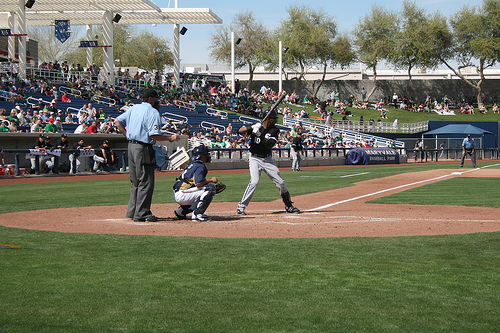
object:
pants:
[123, 142, 162, 223]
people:
[1, 59, 498, 166]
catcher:
[171, 145, 224, 223]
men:
[112, 83, 305, 226]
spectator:
[227, 122, 232, 132]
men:
[1, 53, 378, 153]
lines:
[284, 170, 483, 223]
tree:
[210, 9, 275, 88]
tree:
[254, 5, 356, 97]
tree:
[346, 5, 408, 80]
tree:
[385, 0, 498, 107]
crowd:
[5, 61, 498, 143]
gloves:
[250, 119, 264, 133]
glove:
[249, 120, 264, 130]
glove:
[253, 126, 263, 136]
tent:
[417, 120, 487, 162]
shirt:
[112, 104, 167, 137]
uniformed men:
[170, 145, 225, 221]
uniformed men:
[290, 131, 303, 169]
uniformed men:
[30, 135, 45, 173]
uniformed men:
[93, 137, 114, 173]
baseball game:
[2, 75, 495, 331]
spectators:
[1, 50, 495, 141]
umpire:
[111, 86, 182, 223]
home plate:
[273, 203, 325, 216]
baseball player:
[236, 108, 301, 215]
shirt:
[245, 122, 278, 158]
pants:
[237, 152, 292, 214]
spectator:
[77, 105, 89, 119]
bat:
[252, 87, 288, 135]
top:
[179, 159, 207, 183]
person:
[113, 85, 182, 224]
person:
[234, 113, 299, 220]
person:
[459, 132, 479, 165]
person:
[288, 133, 303, 169]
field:
[6, 159, 482, 331]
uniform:
[106, 103, 168, 220]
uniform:
[233, 118, 295, 218]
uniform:
[171, 159, 224, 224]